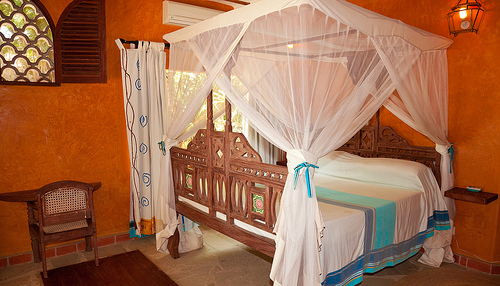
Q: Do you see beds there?
A: Yes, there is a bed.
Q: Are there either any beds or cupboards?
A: Yes, there is a bed.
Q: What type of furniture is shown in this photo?
A: The furniture is a bed.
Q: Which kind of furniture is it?
A: The piece of furniture is a bed.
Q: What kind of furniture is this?
A: That is a bed.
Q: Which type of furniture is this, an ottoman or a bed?
A: That is a bed.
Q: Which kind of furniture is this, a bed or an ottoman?
A: That is a bed.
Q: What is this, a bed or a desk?
A: This is a bed.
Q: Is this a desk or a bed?
A: This is a bed.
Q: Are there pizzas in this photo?
A: No, there are no pizzas.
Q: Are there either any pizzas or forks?
A: No, there are no pizzas or forks.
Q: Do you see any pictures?
A: No, there are no pictures.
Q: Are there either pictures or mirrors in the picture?
A: No, there are no pictures or mirrors.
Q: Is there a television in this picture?
A: No, there are no televisions.